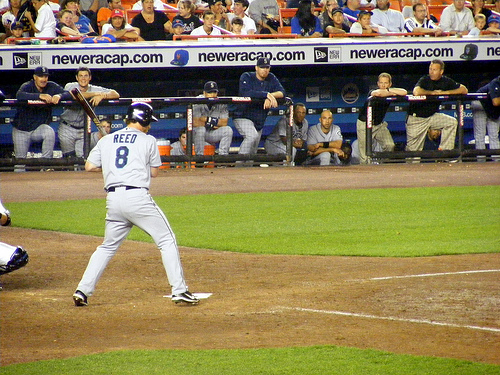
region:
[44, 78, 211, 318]
Batter getting ready to hit the ball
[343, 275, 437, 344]
White chalk on the field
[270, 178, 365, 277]
Grass is short and green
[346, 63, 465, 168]
Players leaning on the fence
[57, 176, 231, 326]
Baseball player wearing pants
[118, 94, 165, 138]
Player wearing a helmet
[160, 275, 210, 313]
Home base beside his feet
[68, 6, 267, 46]
Crowd sitting in the stands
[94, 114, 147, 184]
Name and number on players back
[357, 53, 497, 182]
Players in the dugout waiting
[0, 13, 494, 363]
man playing in baseball game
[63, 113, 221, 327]
man wearing white uniform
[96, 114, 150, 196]
blue writing on uniform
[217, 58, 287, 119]
man wearing blue shirt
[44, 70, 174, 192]
man holding baseball bat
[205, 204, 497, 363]
white lines on field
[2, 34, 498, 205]
people leaning on fence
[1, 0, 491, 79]
people watching baseball game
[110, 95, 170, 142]
man wearing baseball helmet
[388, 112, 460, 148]
man wearing khaki pants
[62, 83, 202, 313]
baseball player up to bat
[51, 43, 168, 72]
sign for neweracap.com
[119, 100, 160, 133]
baseball player wearing batting helmet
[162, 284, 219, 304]
baseball home plate with player's foot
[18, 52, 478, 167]
baseball players in dugout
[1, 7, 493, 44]
fans watching baseball game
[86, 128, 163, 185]
baseball jersey no. 8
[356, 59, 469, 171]
two men in dark shirts and tan pants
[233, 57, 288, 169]
baseball player with arms on fence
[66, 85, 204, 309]
baseball player stepping up to bat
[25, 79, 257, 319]
man is playing baseball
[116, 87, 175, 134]
player is wearing a helmet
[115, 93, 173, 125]
the helmet is dark blue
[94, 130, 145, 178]
the number is 8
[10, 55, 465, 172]
players are in the dugout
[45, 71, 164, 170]
man is holding a bat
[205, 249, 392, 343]
the dirt is brown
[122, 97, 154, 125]
light is shining on the helmet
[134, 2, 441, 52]
people watching the game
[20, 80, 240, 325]
player is ready to hit the ball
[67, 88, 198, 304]
batter at home plate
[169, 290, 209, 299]
home plate in the dirt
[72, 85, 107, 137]
bat in the hitter's hands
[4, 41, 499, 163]
dugout down third base line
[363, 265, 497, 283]
chalk third baseline in dirt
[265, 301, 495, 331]
chalk first baseline in the dirt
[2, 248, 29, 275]
catcher's knee with shin guard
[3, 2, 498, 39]
the stands above the dugout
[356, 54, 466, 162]
two guys with tan pants in the dugout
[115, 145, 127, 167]
blue number 8 on a jersey